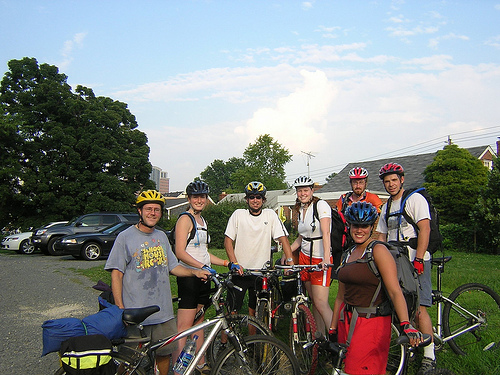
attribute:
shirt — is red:
[334, 191, 383, 245]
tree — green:
[425, 142, 484, 247]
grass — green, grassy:
[458, 254, 500, 284]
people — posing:
[178, 174, 430, 265]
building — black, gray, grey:
[327, 141, 499, 203]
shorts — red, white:
[295, 250, 332, 284]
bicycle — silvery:
[105, 302, 274, 374]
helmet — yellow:
[129, 186, 168, 205]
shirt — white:
[293, 199, 336, 260]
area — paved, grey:
[6, 259, 68, 311]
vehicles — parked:
[6, 209, 132, 263]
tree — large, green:
[6, 56, 145, 219]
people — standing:
[117, 169, 441, 329]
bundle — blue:
[37, 301, 129, 353]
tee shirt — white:
[225, 207, 291, 277]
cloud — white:
[200, 61, 455, 132]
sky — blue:
[80, 10, 332, 89]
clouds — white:
[272, 73, 435, 130]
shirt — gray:
[108, 225, 191, 326]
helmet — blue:
[341, 197, 379, 228]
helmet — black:
[185, 175, 212, 197]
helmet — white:
[290, 171, 317, 188]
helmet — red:
[377, 158, 413, 181]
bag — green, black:
[63, 334, 117, 371]